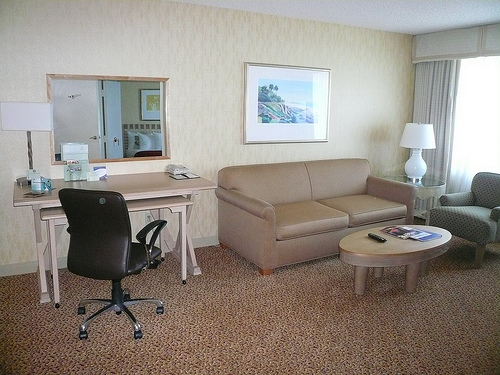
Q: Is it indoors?
A: Yes, it is indoors.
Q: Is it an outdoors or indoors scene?
A: It is indoors.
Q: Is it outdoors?
A: No, it is indoors.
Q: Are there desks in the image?
A: Yes, there is a desk.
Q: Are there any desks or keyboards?
A: Yes, there is a desk.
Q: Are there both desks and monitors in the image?
A: No, there is a desk but no monitors.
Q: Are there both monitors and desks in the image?
A: No, there is a desk but no monitors.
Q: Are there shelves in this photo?
A: No, there are no shelves.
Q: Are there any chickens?
A: No, there are no chickens.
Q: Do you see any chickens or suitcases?
A: No, there are no chickens or suitcases.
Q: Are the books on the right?
A: Yes, the books are on the right of the image.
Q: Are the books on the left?
A: No, the books are on the right of the image.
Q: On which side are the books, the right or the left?
A: The books are on the right of the image.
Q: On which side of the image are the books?
A: The books are on the right of the image.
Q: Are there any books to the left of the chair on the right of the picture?
A: Yes, there are books to the left of the chair.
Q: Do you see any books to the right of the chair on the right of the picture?
A: No, the books are to the left of the chair.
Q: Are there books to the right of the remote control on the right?
A: Yes, there are books to the right of the remote control.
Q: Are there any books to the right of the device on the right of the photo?
A: Yes, there are books to the right of the remote control.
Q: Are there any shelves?
A: No, there are no shelves.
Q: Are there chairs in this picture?
A: Yes, there is a chair.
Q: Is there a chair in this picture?
A: Yes, there is a chair.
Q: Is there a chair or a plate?
A: Yes, there is a chair.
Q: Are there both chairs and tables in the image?
A: Yes, there are both a chair and a table.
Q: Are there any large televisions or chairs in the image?
A: Yes, there is a large chair.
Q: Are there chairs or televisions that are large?
A: Yes, the chair is large.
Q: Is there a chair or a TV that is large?
A: Yes, the chair is large.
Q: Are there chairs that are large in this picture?
A: Yes, there is a large chair.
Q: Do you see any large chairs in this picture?
A: Yes, there is a large chair.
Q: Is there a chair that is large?
A: Yes, there is a chair that is large.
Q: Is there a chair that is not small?
A: Yes, there is a large chair.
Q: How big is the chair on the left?
A: The chair is large.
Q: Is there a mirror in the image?
A: Yes, there is a mirror.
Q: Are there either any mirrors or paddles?
A: Yes, there is a mirror.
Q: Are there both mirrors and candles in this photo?
A: No, there is a mirror but no candles.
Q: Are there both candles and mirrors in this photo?
A: No, there is a mirror but no candles.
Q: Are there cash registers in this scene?
A: No, there are no cash registers.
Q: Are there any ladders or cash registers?
A: No, there are no cash registers or ladders.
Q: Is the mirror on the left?
A: Yes, the mirror is on the left of the image.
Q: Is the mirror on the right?
A: No, the mirror is on the left of the image.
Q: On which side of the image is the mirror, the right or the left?
A: The mirror is on the left of the image.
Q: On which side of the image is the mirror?
A: The mirror is on the left of the image.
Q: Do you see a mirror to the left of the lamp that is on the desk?
A: No, the mirror is to the right of the lamp.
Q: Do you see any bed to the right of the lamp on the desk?
A: No, there is a mirror to the right of the lamp.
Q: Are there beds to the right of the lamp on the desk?
A: No, there is a mirror to the right of the lamp.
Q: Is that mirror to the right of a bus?
A: No, the mirror is to the right of the lamp.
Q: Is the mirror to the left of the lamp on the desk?
A: No, the mirror is to the right of the lamp.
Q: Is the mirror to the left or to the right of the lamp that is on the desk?
A: The mirror is to the right of the lamp.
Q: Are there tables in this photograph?
A: Yes, there is a table.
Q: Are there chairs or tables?
A: Yes, there is a table.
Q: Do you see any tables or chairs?
A: Yes, there is a table.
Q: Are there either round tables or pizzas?
A: Yes, there is a round table.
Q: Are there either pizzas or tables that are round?
A: Yes, the table is round.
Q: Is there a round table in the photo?
A: Yes, there is a round table.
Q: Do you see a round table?
A: Yes, there is a round table.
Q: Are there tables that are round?
A: Yes, there is a table that is round.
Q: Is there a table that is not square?
A: Yes, there is a round table.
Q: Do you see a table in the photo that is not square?
A: Yes, there is a round table.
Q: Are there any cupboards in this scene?
A: No, there are no cupboards.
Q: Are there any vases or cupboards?
A: No, there are no cupboards or vases.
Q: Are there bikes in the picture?
A: No, there are no bikes.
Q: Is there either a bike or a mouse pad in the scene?
A: No, there are no bikes or mouse pads.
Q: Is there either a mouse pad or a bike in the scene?
A: No, there are no bikes or mouse pads.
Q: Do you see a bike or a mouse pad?
A: No, there are no bikes or mouse pads.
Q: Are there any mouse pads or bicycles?
A: No, there are no bicycles or mouse pads.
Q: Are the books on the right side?
A: Yes, the books are on the right of the image.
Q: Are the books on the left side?
A: No, the books are on the right of the image.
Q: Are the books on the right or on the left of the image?
A: The books are on the right of the image.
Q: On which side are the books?
A: The books are on the right of the image.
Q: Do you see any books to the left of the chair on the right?
A: Yes, there are books to the left of the chair.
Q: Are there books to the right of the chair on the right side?
A: No, the books are to the left of the chair.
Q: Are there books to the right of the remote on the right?
A: Yes, there are books to the right of the remote control.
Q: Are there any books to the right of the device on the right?
A: Yes, there are books to the right of the remote control.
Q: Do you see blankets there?
A: No, there are no blankets.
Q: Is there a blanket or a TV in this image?
A: No, there are no blankets or televisions.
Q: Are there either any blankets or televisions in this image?
A: No, there are no blankets or televisions.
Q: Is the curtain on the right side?
A: Yes, the curtain is on the right of the image.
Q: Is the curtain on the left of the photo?
A: No, the curtain is on the right of the image.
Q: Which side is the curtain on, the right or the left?
A: The curtain is on the right of the image.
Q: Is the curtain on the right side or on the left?
A: The curtain is on the right of the image.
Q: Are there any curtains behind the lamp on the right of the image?
A: Yes, there is a curtain behind the lamp.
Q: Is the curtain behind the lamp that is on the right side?
A: Yes, the curtain is behind the lamp.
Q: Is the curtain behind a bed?
A: No, the curtain is behind the lamp.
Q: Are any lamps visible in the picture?
A: Yes, there is a lamp.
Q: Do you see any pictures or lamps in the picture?
A: Yes, there is a lamp.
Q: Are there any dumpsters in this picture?
A: No, there are no dumpsters.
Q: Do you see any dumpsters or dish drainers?
A: No, there are no dumpsters or dish drainers.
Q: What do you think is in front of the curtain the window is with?
A: The lamp is in front of the curtain.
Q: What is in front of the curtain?
A: The lamp is in front of the curtain.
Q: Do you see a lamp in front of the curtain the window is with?
A: Yes, there is a lamp in front of the curtain.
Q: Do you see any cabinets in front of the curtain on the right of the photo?
A: No, there is a lamp in front of the curtain.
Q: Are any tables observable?
A: Yes, there is a table.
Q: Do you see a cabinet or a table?
A: Yes, there is a table.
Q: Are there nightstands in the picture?
A: No, there are no nightstands.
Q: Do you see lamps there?
A: Yes, there is a lamp.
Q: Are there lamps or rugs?
A: Yes, there is a lamp.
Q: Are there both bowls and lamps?
A: No, there is a lamp but no bowls.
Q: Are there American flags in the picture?
A: No, there are no American flags.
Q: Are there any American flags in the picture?
A: No, there are no American flags.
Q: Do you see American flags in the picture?
A: No, there are no American flags.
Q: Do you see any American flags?
A: No, there are no American flags.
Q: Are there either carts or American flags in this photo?
A: No, there are no American flags or carts.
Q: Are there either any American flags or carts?
A: No, there are no American flags or carts.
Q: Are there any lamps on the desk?
A: Yes, there is a lamp on the desk.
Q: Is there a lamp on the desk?
A: Yes, there is a lamp on the desk.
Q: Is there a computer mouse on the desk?
A: No, there is a lamp on the desk.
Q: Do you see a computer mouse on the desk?
A: No, there is a lamp on the desk.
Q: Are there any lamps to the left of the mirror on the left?
A: Yes, there is a lamp to the left of the mirror.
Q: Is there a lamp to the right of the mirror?
A: No, the lamp is to the left of the mirror.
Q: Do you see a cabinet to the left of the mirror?
A: No, there is a lamp to the left of the mirror.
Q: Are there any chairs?
A: Yes, there is a chair.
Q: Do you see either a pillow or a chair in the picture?
A: Yes, there is a chair.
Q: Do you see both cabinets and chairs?
A: No, there is a chair but no cabinets.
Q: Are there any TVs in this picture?
A: No, there are no tvs.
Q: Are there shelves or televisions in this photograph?
A: No, there are no televisions or shelves.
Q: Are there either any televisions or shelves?
A: No, there are no televisions or shelves.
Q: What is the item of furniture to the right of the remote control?
A: The piece of furniture is a chair.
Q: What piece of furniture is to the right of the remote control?
A: The piece of furniture is a chair.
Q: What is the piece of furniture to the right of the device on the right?
A: The piece of furniture is a chair.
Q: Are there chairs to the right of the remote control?
A: Yes, there is a chair to the right of the remote control.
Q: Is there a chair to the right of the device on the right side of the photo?
A: Yes, there is a chair to the right of the remote control.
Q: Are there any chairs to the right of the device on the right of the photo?
A: Yes, there is a chair to the right of the remote control.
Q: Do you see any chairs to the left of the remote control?
A: No, the chair is to the right of the remote control.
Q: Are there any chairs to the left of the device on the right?
A: No, the chair is to the right of the remote control.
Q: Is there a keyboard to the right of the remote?
A: No, there is a chair to the right of the remote.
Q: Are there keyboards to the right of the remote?
A: No, there is a chair to the right of the remote.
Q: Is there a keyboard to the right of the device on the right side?
A: No, there is a chair to the right of the remote.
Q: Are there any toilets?
A: No, there are no toilets.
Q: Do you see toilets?
A: No, there are no toilets.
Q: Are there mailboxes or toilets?
A: No, there are no toilets or mailboxes.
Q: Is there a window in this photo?
A: Yes, there is a window.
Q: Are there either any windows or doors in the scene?
A: Yes, there is a window.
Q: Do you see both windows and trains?
A: No, there is a window but no trains.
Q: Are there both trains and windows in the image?
A: No, there is a window but no trains.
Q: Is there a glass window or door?
A: Yes, there is a glass window.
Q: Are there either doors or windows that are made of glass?
A: Yes, the window is made of glass.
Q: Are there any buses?
A: No, there are no buses.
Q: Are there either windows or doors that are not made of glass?
A: No, there is a window but it is made of glass.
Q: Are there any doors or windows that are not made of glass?
A: No, there is a window but it is made of glass.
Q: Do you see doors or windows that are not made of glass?
A: No, there is a window but it is made of glass.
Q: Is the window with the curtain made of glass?
A: Yes, the window is made of glass.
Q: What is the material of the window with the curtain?
A: The window is made of glass.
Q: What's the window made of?
A: The window is made of glass.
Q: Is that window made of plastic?
A: No, the window is made of glass.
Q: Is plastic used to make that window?
A: No, the window is made of glass.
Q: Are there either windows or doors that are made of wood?
A: No, there is a window but it is made of glass.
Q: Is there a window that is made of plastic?
A: No, there is a window but it is made of glass.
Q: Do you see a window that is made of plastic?
A: No, there is a window but it is made of glass.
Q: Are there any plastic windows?
A: No, there is a window but it is made of glass.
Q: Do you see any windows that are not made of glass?
A: No, there is a window but it is made of glass.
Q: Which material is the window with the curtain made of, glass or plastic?
A: The window is made of glass.